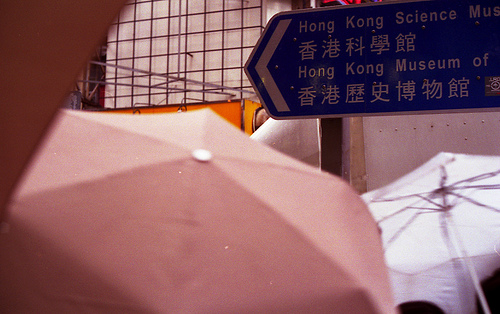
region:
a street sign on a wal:
[150, 5, 496, 201]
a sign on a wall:
[203, 8, 499, 187]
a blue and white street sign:
[240, 25, 494, 193]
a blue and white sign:
[232, 11, 497, 209]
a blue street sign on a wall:
[229, 11, 498, 186]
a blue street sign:
[247, 11, 499, 139]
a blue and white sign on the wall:
[228, 15, 495, 191]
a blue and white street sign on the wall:
[250, 6, 499, 146]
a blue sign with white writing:
[246, 9, 494, 182]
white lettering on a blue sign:
[215, 15, 465, 136]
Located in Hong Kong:
[245, 7, 492, 122]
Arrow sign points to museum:
[250, 9, 498, 129]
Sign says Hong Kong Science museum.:
[286, 9, 494, 26]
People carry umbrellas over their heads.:
[10, 110, 496, 303]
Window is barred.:
[100, 7, 250, 104]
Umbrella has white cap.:
[175, 130, 226, 176]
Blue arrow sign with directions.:
[248, 12, 490, 100]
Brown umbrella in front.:
[11, 125, 351, 305]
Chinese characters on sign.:
[285, 30, 415, 57]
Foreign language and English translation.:
[281, 11, 498, 111]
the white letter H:
[291, 58, 311, 83]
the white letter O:
[308, 65, 318, 79]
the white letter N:
[312, 63, 329, 83]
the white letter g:
[322, 64, 337, 80]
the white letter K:
[345, 57, 357, 81]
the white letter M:
[392, 56, 414, 77]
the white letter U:
[408, 58, 420, 76]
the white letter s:
[416, 59, 428, 74]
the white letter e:
[426, 57, 438, 71]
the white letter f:
[476, 48, 497, 78]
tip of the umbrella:
[183, 140, 225, 175]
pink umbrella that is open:
[211, 195, 307, 266]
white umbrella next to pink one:
[393, 155, 473, 203]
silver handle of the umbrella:
[436, 223, 482, 278]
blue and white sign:
[302, 13, 453, 112]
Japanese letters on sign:
[285, 79, 370, 111]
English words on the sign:
[288, 53, 420, 88]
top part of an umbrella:
[193, 169, 299, 238]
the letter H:
[283, 62, 315, 92]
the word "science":
[391, 2, 457, 34]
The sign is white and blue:
[241, 0, 498, 126]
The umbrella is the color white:
[10, 106, 403, 311]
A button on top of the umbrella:
[184, 143, 219, 170]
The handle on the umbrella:
[428, 202, 497, 312]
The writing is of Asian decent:
[291, 73, 483, 108]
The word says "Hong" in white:
[292, 55, 337, 84]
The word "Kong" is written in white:
[341, 58, 388, 79]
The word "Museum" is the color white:
[393, 53, 463, 77]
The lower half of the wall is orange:
[83, 89, 267, 141]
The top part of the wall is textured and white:
[101, 2, 268, 104]